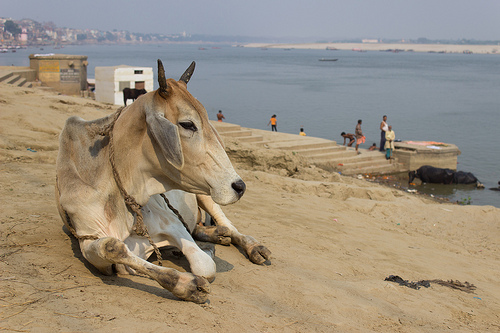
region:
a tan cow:
[54, 62, 276, 299]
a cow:
[52, 59, 277, 311]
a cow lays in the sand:
[54, 61, 279, 312]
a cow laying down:
[54, 48, 276, 309]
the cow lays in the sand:
[54, 37, 279, 307]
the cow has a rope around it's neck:
[55, 55, 280, 302]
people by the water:
[209, 98, 451, 183]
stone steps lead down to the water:
[19, 68, 424, 187]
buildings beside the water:
[11, 13, 258, 63]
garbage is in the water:
[344, 163, 479, 201]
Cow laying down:
[56, 59, 271, 303]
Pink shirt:
[261, 112, 282, 124]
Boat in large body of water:
[311, 55, 346, 61]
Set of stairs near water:
[277, 135, 380, 168]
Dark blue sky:
[0, 0, 498, 30]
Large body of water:
[230, 63, 497, 109]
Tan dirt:
[318, 205, 489, 263]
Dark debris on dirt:
[377, 270, 482, 296]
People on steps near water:
[213, 105, 418, 142]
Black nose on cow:
[226, 180, 250, 195]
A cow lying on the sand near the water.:
[55, 59, 273, 306]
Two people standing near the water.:
[380, 112, 396, 162]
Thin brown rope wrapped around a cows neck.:
[102, 106, 162, 273]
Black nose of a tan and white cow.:
[231, 177, 244, 197]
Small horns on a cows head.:
[155, 58, 197, 92]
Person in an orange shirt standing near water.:
[270, 112, 277, 131]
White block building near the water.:
[92, 64, 154, 107]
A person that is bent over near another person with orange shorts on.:
[339, 130, 359, 151]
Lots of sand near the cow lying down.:
[227, 274, 264, 314]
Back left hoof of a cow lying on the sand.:
[246, 246, 274, 266]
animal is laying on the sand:
[31, 63, 304, 310]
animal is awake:
[40, 53, 294, 298]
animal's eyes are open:
[168, 103, 203, 140]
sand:
[241, 134, 476, 327]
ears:
[140, 108, 200, 171]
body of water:
[3, 18, 494, 180]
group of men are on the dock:
[216, 91, 420, 153]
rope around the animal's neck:
[74, 93, 166, 240]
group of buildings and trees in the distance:
[0, 10, 174, 59]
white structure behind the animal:
[73, 48, 197, 150]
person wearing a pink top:
[256, 102, 287, 133]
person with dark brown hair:
[264, 106, 286, 136]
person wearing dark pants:
[258, 103, 290, 141]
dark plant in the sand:
[388, 268, 486, 310]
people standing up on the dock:
[373, 106, 403, 153]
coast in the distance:
[235, 31, 495, 84]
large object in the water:
[311, 52, 353, 74]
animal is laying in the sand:
[41, 57, 323, 327]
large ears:
[131, 106, 204, 177]